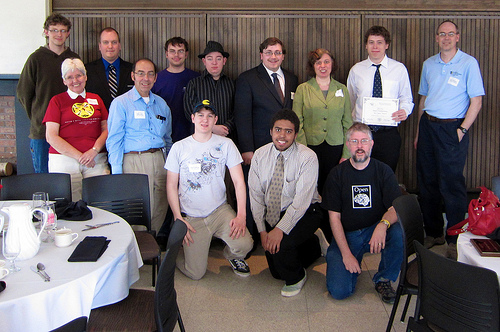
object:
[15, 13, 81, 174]
man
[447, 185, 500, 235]
purse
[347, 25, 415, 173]
boy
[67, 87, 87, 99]
collar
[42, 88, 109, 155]
shirt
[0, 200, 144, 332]
table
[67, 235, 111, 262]
napkin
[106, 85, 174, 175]
shirt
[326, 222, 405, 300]
jeans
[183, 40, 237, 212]
boy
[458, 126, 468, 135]
watch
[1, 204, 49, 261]
container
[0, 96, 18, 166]
brick wall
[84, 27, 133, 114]
man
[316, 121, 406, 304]
man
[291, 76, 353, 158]
blazer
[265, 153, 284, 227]
tie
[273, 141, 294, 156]
neck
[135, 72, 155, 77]
eyeglasses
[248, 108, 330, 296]
man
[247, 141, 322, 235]
shirt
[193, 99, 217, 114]
baseball hat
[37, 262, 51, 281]
spoon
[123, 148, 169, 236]
pants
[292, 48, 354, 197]
people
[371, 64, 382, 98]
neck tie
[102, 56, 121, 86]
blue shirt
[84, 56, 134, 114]
black shirt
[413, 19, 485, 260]
man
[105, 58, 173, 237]
man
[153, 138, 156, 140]
button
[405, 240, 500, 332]
chair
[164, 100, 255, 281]
boy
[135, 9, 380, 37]
wood paneling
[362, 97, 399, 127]
certificate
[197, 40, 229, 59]
fedora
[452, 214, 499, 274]
table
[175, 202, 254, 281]
pants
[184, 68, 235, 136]
shirt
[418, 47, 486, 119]
shirt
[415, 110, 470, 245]
pants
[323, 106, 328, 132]
buttons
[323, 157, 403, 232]
shirt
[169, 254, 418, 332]
floor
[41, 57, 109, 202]
woman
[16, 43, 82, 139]
sweater